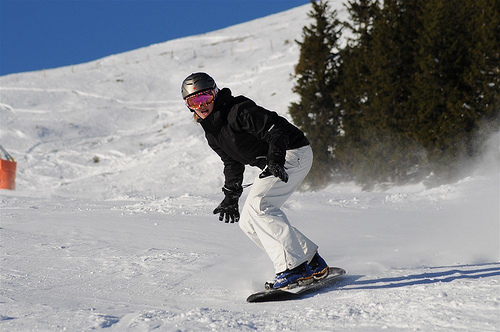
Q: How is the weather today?
A: It is clear.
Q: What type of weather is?
A: It is clear.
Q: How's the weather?
A: It is clear.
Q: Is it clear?
A: Yes, it is clear.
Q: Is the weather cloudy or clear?
A: It is clear.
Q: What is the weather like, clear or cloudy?
A: It is clear.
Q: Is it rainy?
A: No, it is clear.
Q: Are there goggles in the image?
A: Yes, there are goggles.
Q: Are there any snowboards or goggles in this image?
A: Yes, there are goggles.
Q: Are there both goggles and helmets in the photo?
A: Yes, there are both goggles and a helmet.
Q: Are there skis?
A: No, there are no skis.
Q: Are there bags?
A: No, there are no bags.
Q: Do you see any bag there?
A: No, there are no bags.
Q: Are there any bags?
A: No, there are no bags.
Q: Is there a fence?
A: No, there are no fences.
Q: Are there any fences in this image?
A: No, there are no fences.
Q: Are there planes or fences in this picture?
A: No, there are no fences or planes.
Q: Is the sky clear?
A: Yes, the sky is clear.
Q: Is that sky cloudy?
A: No, the sky is clear.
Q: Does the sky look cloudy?
A: No, the sky is clear.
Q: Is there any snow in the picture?
A: Yes, there is snow.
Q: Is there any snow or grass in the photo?
A: Yes, there is snow.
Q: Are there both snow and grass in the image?
A: No, there is snow but no grass.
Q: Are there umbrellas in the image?
A: No, there are no umbrellas.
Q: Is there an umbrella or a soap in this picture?
A: No, there are no umbrellas or soaps.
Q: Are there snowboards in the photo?
A: Yes, there is a snowboard.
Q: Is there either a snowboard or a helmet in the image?
A: Yes, there is a snowboard.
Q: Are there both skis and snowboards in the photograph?
A: No, there is a snowboard but no skis.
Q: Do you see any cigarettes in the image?
A: No, there are no cigarettes.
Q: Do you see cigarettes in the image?
A: No, there are no cigarettes.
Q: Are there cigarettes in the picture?
A: No, there are no cigarettes.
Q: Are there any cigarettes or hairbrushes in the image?
A: No, there are no cigarettes or hairbrushes.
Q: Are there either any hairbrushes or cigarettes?
A: No, there are no cigarettes or hairbrushes.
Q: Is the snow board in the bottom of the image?
A: Yes, the snow board is in the bottom of the image.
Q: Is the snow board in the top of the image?
A: No, the snow board is in the bottom of the image.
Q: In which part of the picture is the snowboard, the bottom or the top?
A: The snowboard is in the bottom of the image.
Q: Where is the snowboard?
A: The snowboard is on the snow.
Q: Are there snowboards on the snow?
A: Yes, there is a snowboard on the snow.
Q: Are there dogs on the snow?
A: No, there is a snowboard on the snow.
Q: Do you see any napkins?
A: No, there are no napkins.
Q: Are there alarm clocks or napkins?
A: No, there are no napkins or alarm clocks.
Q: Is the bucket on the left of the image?
A: Yes, the bucket is on the left of the image.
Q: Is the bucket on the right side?
A: No, the bucket is on the left of the image.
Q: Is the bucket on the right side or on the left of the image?
A: The bucket is on the left of the image.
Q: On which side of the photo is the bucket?
A: The bucket is on the left of the image.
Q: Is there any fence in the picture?
A: No, there are no fences.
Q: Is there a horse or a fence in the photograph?
A: No, there are no fences or horses.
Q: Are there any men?
A: No, there are no men.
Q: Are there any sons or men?
A: No, there are no men or sons.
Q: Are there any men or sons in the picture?
A: No, there are no men or sons.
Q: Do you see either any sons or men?
A: No, there are no men or sons.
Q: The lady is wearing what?
A: The lady is wearing pants.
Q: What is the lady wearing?
A: The lady is wearing pants.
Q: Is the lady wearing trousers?
A: Yes, the lady is wearing trousers.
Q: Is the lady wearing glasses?
A: No, the lady is wearing trousers.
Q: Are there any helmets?
A: Yes, there is a helmet.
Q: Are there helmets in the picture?
A: Yes, there is a helmet.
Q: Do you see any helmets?
A: Yes, there is a helmet.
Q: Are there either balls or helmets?
A: Yes, there is a helmet.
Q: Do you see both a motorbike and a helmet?
A: No, there is a helmet but no motorcycles.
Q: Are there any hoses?
A: No, there are no hoses.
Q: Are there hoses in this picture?
A: No, there are no hoses.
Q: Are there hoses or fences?
A: No, there are no hoses or fences.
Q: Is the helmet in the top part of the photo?
A: Yes, the helmet is in the top of the image.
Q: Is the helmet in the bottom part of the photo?
A: No, the helmet is in the top of the image.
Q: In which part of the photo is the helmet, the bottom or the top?
A: The helmet is in the top of the image.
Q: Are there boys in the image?
A: No, there are no boys.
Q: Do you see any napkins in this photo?
A: No, there are no napkins.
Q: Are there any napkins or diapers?
A: No, there are no napkins or diapers.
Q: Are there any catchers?
A: No, there are no catchers.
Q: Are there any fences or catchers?
A: No, there are no catchers or fences.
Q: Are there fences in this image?
A: No, there are no fences.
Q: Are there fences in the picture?
A: No, there are no fences.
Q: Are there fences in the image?
A: No, there are no fences.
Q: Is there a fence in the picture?
A: No, there are no fences.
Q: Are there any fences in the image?
A: No, there are no fences.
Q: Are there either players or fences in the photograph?
A: No, there are no fences or players.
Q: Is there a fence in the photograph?
A: No, there are no fences.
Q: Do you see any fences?
A: No, there are no fences.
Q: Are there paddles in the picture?
A: No, there are no paddles.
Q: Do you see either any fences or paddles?
A: No, there are no paddles or fences.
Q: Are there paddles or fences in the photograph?
A: No, there are no paddles or fences.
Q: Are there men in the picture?
A: No, there are no men.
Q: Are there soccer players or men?
A: No, there are no men or soccer players.